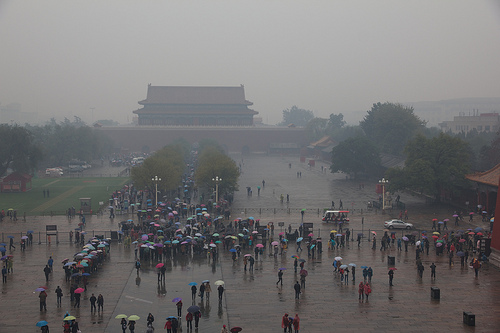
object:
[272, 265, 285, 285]
peope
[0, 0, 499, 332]
rain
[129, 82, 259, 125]
building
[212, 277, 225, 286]
umbrellas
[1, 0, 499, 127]
sky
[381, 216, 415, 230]
car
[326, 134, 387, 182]
tree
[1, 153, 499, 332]
ground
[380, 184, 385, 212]
post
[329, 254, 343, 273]
person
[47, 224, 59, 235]
object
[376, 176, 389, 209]
light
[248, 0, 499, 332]
right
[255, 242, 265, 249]
umbrella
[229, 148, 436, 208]
plaza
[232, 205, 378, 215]
fence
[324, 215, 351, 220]
chair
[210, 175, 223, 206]
street light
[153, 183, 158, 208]
pole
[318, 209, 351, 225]
vehicle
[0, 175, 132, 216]
field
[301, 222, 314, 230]
sign